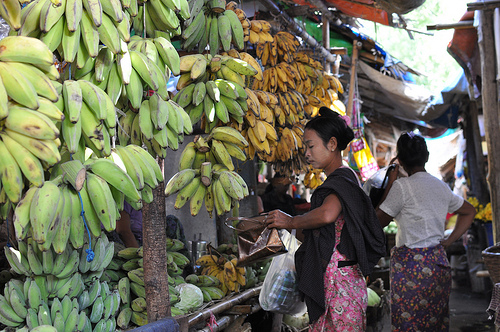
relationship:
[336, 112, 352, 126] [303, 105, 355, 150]
clip in hair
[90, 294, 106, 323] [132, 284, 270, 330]
bananas on table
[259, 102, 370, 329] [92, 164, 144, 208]
women buying bananas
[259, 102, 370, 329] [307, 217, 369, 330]
women in garmet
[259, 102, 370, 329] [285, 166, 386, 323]
women in blanket